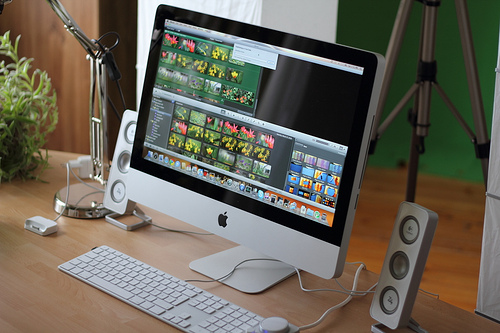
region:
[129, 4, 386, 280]
the computer screen on the desk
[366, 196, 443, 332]
the speaker on the desk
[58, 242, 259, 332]
the keyboard on the desk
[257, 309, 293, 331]
the knob on the keyboard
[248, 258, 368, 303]
the wires on the desktop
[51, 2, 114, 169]
the stand for the desk lamp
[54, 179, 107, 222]
the silver base of the lamp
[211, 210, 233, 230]
the black apple logo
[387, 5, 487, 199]
the tripod behind the computer screen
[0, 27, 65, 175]
the plant on the desk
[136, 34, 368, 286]
a computer screen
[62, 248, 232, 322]
a computer keyboard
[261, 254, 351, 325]
cords on the desk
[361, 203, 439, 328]
speakers on the desk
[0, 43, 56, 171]
a plant on the desk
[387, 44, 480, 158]
a green wall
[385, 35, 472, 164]
the base of a tripod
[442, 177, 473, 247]
the hardwood floor under the desk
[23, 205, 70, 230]
a charger on the desk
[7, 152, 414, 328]
a wooden desk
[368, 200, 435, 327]
A speaker by the computer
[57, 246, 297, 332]
A keyboard on the desk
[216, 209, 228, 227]
An Apple logo on the monitor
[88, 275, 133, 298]
The spacebar on the keyboard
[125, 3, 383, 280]
The monitor of the computer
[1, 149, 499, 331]
A desk beneath the computer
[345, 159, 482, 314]
The floor beneath the desk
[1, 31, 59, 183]
A plant on the desk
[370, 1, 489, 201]
A tripod near the monitor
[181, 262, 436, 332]
Wires connected to the keyboard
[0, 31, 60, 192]
Plant on wooden desk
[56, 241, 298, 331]
White keyboard on desk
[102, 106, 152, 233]
Small speaker next to computer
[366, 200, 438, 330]
Small speaker next to computer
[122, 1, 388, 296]
Black and white Apple computer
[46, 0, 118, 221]
Silver base of table lamp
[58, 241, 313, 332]
Computer keyboard with wire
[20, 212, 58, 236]
Small white electronic device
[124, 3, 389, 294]
Computer monitor with website page on it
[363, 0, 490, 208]
Silver tripod on floor